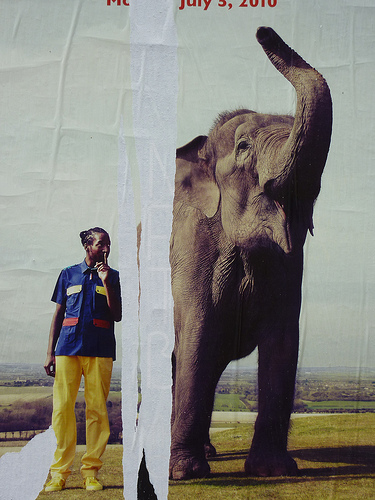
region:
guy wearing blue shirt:
[23, 208, 146, 499]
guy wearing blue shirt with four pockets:
[37, 216, 129, 497]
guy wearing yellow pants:
[34, 213, 129, 498]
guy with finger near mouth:
[31, 211, 133, 498]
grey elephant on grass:
[137, 10, 368, 492]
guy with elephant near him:
[24, 26, 336, 496]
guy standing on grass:
[37, 225, 141, 498]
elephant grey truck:
[232, 14, 353, 189]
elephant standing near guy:
[18, 17, 343, 497]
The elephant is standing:
[161, 35, 343, 481]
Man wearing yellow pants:
[43, 356, 113, 476]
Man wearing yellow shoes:
[35, 472, 111, 496]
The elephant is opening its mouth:
[209, 31, 340, 265]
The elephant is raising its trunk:
[196, 18, 335, 260]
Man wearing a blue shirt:
[44, 216, 121, 368]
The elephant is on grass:
[168, 27, 336, 484]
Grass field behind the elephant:
[300, 395, 366, 415]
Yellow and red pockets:
[64, 280, 110, 342]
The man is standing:
[40, 224, 115, 495]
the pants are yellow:
[44, 357, 121, 468]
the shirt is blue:
[51, 269, 115, 356]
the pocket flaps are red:
[58, 312, 118, 337]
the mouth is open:
[247, 173, 321, 252]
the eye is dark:
[233, 135, 254, 155]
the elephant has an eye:
[234, 133, 253, 148]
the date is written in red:
[173, 1, 286, 14]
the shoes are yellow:
[39, 473, 115, 493]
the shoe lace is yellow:
[85, 473, 101, 484]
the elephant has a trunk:
[246, 23, 347, 171]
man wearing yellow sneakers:
[41, 224, 121, 495]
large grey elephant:
[172, 25, 330, 479]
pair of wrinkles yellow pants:
[48, 353, 112, 475]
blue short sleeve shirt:
[48, 258, 122, 361]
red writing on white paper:
[103, 0, 282, 10]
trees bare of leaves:
[5, 396, 123, 438]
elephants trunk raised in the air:
[253, 24, 334, 209]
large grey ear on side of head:
[172, 132, 220, 220]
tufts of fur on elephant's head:
[202, 102, 249, 139]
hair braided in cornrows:
[73, 223, 109, 249]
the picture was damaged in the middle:
[115, 43, 164, 499]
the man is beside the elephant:
[35, 220, 120, 492]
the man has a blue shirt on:
[43, 257, 122, 360]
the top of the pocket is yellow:
[61, 286, 82, 295]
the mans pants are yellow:
[51, 339, 118, 479]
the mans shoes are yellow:
[46, 474, 72, 497]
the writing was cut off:
[175, 0, 293, 15]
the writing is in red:
[176, 1, 278, 11]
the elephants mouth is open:
[140, 21, 345, 495]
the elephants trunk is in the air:
[205, 21, 343, 223]